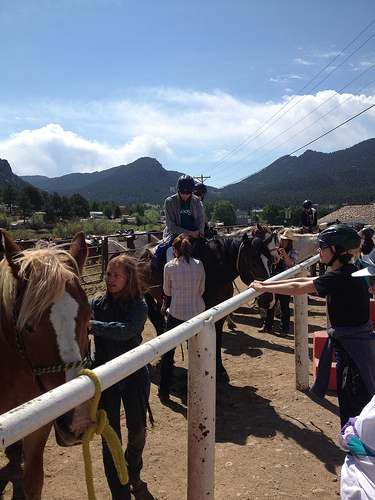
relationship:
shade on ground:
[140, 360, 374, 486] [0, 229, 373, 499]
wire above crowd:
[202, 19, 374, 191] [90, 226, 374, 494]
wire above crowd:
[268, 120, 297, 140] [90, 226, 374, 494]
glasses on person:
[174, 186, 195, 199] [150, 175, 219, 304]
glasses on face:
[174, 186, 195, 199] [175, 189, 191, 200]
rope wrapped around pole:
[52, 369, 128, 498] [3, 254, 320, 444]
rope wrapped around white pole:
[52, 369, 128, 498] [1, 317, 188, 451]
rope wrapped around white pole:
[41, 370, 146, 485] [84, 231, 346, 406]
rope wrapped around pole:
[52, 369, 128, 498] [3, 249, 321, 498]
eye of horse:
[31, 307, 64, 341] [0, 256, 125, 467]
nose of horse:
[29, 344, 102, 446] [2, 226, 103, 495]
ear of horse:
[0, 228, 28, 276] [2, 226, 103, 495]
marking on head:
[46, 284, 83, 378] [7, 222, 106, 389]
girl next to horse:
[88, 252, 152, 495] [2, 226, 103, 495]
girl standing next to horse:
[90, 240, 150, 398] [8, 227, 96, 430]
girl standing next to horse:
[88, 252, 152, 495] [0, 225, 90, 498]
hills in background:
[3, 133, 372, 204] [1, 141, 373, 214]